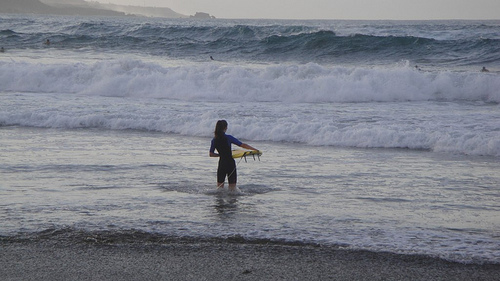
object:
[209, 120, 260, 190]
surfer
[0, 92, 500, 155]
waves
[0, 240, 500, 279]
beach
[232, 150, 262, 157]
surfboard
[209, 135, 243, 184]
wetsuit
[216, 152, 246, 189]
rope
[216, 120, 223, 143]
ponytail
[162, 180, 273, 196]
ripples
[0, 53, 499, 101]
wave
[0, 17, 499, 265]
sea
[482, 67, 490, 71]
person